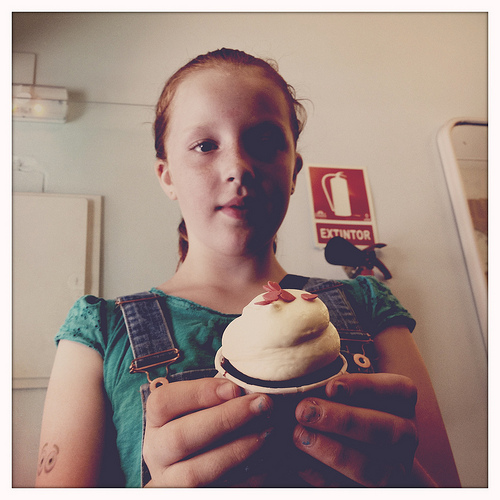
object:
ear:
[289, 148, 306, 195]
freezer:
[13, 192, 101, 489]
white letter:
[361, 223, 375, 243]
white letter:
[341, 225, 355, 245]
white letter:
[314, 223, 331, 244]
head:
[157, 46, 294, 273]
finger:
[326, 372, 416, 399]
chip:
[300, 289, 317, 300]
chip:
[278, 287, 296, 303]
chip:
[262, 279, 281, 291]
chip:
[256, 292, 277, 306]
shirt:
[56, 275, 416, 490]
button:
[352, 352, 372, 370]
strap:
[303, 270, 373, 351]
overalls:
[111, 272, 392, 491]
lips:
[215, 192, 267, 223]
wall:
[0, 47, 487, 466]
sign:
[302, 161, 378, 247]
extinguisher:
[322, 238, 394, 281]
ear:
[155, 155, 177, 199]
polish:
[218, 394, 359, 459]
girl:
[1, 47, 463, 479]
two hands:
[146, 384, 420, 486]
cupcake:
[213, 281, 348, 394]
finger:
[143, 377, 238, 423]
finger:
[143, 391, 271, 455]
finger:
[151, 425, 277, 483]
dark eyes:
[187, 137, 280, 154]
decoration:
[262, 291, 279, 302]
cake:
[213, 288, 348, 395]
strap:
[113, 291, 185, 378]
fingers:
[291, 373, 419, 483]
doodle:
[36, 441, 60, 474]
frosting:
[215, 280, 342, 375]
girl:
[95, 38, 426, 458]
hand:
[136, 375, 274, 487]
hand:
[297, 367, 426, 484]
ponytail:
[169, 218, 188, 262]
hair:
[151, 40, 305, 260]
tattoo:
[30, 432, 66, 479]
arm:
[41, 340, 102, 475]